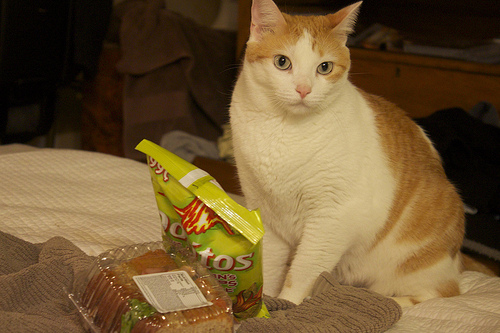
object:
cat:
[229, 0, 464, 305]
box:
[64, 239, 232, 332]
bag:
[135, 137, 271, 318]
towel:
[121, 0, 229, 160]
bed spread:
[2, 141, 500, 332]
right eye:
[314, 60, 333, 76]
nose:
[294, 84, 312, 96]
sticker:
[131, 270, 213, 313]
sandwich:
[80, 248, 232, 331]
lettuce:
[120, 298, 152, 332]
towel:
[0, 233, 402, 332]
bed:
[0, 144, 499, 332]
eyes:
[273, 53, 291, 70]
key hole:
[391, 64, 404, 78]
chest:
[346, 47, 499, 118]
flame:
[173, 195, 232, 235]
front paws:
[275, 292, 303, 305]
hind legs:
[369, 270, 457, 308]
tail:
[444, 247, 461, 295]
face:
[262, 25, 348, 113]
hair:
[342, 10, 356, 36]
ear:
[328, 1, 363, 36]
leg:
[275, 216, 352, 304]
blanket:
[1, 139, 499, 331]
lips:
[287, 99, 312, 106]